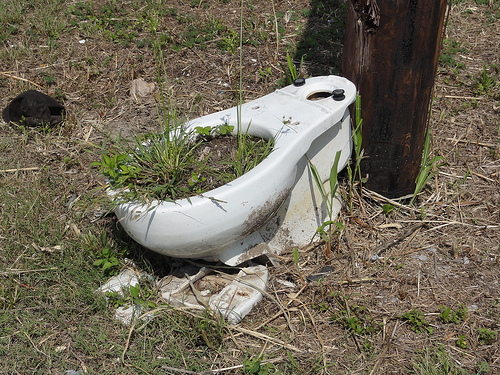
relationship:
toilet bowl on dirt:
[97, 67, 355, 274] [4, 3, 498, 373]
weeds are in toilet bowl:
[99, 124, 266, 210] [97, 67, 355, 274]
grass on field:
[311, 247, 406, 372] [0, 0, 498, 373]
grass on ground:
[7, 276, 84, 363] [353, 206, 473, 341]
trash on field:
[85, 259, 272, 350] [0, 0, 498, 373]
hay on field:
[379, 197, 472, 234] [0, 0, 498, 373]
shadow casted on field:
[295, 15, 347, 72] [0, 0, 498, 373]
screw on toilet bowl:
[331, 88, 344, 100] [97, 67, 355, 274]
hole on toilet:
[304, 85, 334, 105] [103, 70, 362, 262]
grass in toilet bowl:
[104, 128, 211, 202] [98, 117, 275, 243]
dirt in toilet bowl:
[189, 133, 243, 182] [98, 117, 275, 243]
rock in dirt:
[126, 75, 161, 107] [4, 3, 498, 373]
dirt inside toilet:
[134, 134, 272, 202] [103, 70, 362, 262]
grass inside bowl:
[169, 140, 269, 192] [135, 73, 330, 215]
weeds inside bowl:
[99, 120, 276, 200] [135, 73, 330, 215]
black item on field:
[1, 89, 67, 127] [0, 0, 498, 373]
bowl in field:
[152, 89, 319, 234] [81, 19, 462, 270]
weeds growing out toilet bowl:
[99, 120, 276, 200] [102, 71, 362, 290]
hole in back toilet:
[304, 91, 335, 103] [103, 70, 362, 262]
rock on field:
[1, 89, 68, 129] [0, 0, 498, 373]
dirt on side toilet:
[245, 196, 292, 250] [92, 68, 392, 282]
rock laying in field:
[126, 78, 161, 107] [2, 2, 498, 374]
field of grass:
[2, 2, 498, 374] [86, 1, 239, 61]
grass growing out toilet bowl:
[87, 101, 252, 205] [85, 68, 364, 328]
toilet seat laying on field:
[92, 247, 270, 327] [0, 0, 498, 373]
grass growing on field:
[11, 9, 245, 62] [0, 0, 498, 373]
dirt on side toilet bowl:
[232, 188, 298, 268] [102, 72, 364, 265]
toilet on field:
[103, 70, 362, 262] [0, 0, 498, 373]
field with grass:
[0, 0, 498, 373] [98, 120, 271, 207]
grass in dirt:
[330, 273, 484, 353] [349, 245, 450, 335]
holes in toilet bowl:
[244, 90, 292, 141] [102, 71, 362, 290]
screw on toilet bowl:
[328, 87, 348, 104] [102, 72, 364, 265]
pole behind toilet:
[339, 0, 451, 207] [103, 70, 362, 262]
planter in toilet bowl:
[86, 94, 246, 204] [109, 72, 369, 279]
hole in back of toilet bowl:
[304, 91, 335, 103] [97, 67, 355, 274]